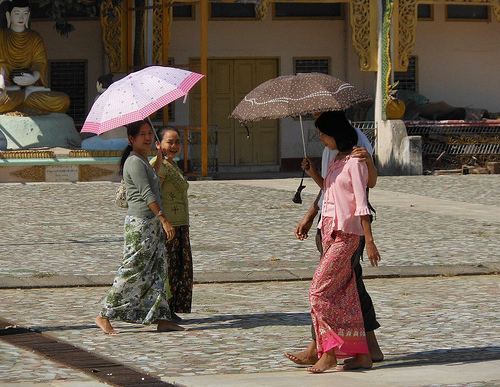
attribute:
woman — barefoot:
[297, 112, 381, 375]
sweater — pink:
[316, 157, 376, 234]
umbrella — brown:
[236, 70, 369, 165]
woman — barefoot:
[99, 123, 188, 334]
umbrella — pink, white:
[81, 65, 207, 160]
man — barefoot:
[307, 107, 382, 177]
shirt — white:
[316, 123, 373, 176]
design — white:
[242, 83, 361, 105]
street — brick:
[3, 176, 499, 385]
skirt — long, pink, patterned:
[311, 217, 370, 354]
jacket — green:
[119, 157, 164, 221]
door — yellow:
[188, 57, 282, 173]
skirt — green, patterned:
[106, 215, 177, 325]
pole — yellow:
[196, 8, 211, 171]